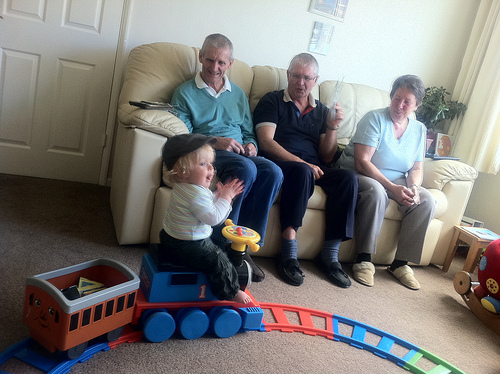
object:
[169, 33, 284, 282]
man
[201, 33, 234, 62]
hair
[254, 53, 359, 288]
man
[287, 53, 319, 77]
hair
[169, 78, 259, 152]
sweater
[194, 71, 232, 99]
shirt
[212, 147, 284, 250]
jeans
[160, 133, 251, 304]
child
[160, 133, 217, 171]
hat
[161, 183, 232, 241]
shirt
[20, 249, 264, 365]
train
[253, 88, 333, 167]
shirt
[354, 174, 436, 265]
pants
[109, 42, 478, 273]
couch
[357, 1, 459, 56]
wall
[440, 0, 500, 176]
curtain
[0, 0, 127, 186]
door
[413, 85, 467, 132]
plant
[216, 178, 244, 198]
hands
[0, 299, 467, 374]
tracks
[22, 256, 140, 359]
train car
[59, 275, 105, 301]
toys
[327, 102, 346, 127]
left hand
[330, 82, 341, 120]
object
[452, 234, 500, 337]
rocking toy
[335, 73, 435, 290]
people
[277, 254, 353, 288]
shoes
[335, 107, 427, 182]
shirt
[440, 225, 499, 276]
table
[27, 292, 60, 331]
face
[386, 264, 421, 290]
slippers